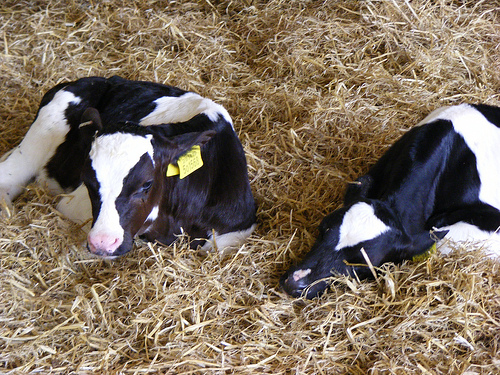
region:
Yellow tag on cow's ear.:
[166, 150, 220, 183]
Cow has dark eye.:
[138, 175, 158, 193]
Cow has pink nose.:
[91, 229, 129, 251]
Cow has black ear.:
[164, 126, 211, 151]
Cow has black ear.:
[74, 115, 110, 135]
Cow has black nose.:
[281, 271, 313, 298]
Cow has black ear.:
[411, 226, 450, 253]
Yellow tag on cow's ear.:
[418, 240, 435, 257]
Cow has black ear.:
[343, 170, 378, 209]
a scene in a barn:
[4, 5, 497, 374]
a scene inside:
[2, 0, 497, 372]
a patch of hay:
[4, 3, 499, 371]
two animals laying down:
[5, 63, 497, 337]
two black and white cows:
[1, 46, 494, 335]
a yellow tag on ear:
[163, 128, 214, 186]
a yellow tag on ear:
[390, 224, 454, 276]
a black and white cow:
[0, 70, 261, 269]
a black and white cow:
[274, 95, 499, 330]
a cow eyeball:
[135, 177, 162, 195]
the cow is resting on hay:
[19, 56, 229, 276]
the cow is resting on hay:
[27, 62, 259, 321]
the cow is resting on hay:
[12, 37, 261, 310]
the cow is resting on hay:
[22, 25, 265, 325]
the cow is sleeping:
[272, 137, 424, 373]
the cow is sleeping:
[262, 144, 412, 359]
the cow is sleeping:
[265, 168, 418, 342]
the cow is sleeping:
[279, 176, 432, 364]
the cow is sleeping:
[241, 142, 435, 355]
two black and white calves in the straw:
[2, 55, 499, 306]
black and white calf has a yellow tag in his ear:
[9, 57, 269, 284]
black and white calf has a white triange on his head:
[283, 72, 497, 310]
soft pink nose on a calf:
[87, 230, 127, 255]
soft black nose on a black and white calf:
[283, 269, 310, 296]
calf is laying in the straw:
[276, 79, 494, 312]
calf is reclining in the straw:
[5, 56, 268, 290]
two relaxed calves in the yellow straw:
[4, 57, 495, 301]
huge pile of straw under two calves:
[3, 2, 490, 374]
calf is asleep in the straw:
[270, 82, 492, 322]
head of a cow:
[47, 95, 164, 280]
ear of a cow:
[169, 121, 213, 158]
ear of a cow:
[56, 102, 97, 154]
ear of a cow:
[333, 176, 394, 223]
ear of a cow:
[397, 202, 488, 290]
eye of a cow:
[80, 168, 101, 198]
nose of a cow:
[80, 223, 135, 263]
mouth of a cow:
[267, 278, 335, 310]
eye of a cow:
[305, 222, 332, 244]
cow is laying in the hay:
[0, 77, 259, 262]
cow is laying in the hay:
[281, 100, 498, 299]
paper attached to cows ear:
[168, 145, 205, 182]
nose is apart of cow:
[283, 271, 308, 293]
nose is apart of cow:
[86, 233, 120, 253]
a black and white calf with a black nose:
[280, 100, 498, 297]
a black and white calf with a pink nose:
[0, 72, 255, 257]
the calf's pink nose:
[85, 230, 122, 252]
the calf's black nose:
[277, 270, 307, 295]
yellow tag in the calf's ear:
[165, 145, 205, 180]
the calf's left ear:
[400, 230, 450, 260]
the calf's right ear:
[343, 173, 373, 205]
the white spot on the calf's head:
[334, 200, 390, 252]